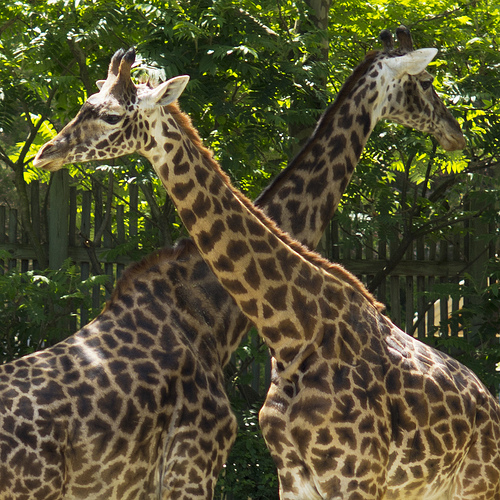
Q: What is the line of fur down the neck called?
A: Mane.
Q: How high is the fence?
A: Approximately 10-12 feet judging from the height of adult giraffes.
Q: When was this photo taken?
A: The middle of the day.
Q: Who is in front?
A: The left facing giraffe.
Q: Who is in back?
A: The right facing giraffe.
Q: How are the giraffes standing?
A: Facing away from each other.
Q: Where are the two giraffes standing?
A: Side by side.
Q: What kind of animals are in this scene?
A: Giraffes.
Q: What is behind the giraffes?
A: A fence.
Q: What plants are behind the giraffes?
A: Trees.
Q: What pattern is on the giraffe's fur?
A: Brown spots.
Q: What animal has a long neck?
A: The giraffe.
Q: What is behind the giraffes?
A: The fence.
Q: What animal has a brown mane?
A: The giraffe.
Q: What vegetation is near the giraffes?
A: Trees.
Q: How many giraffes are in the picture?
A: Two.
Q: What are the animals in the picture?
A: Giraffes.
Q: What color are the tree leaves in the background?
A: Green.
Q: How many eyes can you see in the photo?
A: Two.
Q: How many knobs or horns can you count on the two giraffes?
A: Four.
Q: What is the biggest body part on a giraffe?
A: Neck.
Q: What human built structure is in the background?
A: Fence.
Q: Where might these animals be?
A: Zoo.